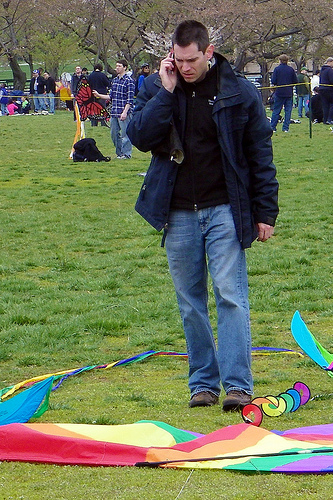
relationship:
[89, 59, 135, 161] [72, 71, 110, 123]
people holding butterfly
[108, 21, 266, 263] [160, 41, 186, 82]
guy talking on a cell phone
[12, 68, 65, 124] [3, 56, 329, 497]
people gathering on a field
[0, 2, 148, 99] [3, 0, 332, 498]
trees growing in a park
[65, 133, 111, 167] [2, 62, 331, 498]
bag sitting on ground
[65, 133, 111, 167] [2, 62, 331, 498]
bag on ground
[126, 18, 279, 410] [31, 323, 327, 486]
person standing on ground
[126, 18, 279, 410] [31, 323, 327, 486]
person on ground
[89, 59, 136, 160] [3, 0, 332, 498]
people gathering in park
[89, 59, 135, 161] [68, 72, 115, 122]
people holding kite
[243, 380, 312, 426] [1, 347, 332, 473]
tail of kite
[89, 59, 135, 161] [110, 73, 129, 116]
people wearing plaid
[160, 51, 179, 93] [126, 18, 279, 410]
hand of a person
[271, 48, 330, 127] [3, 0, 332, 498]
people standing in park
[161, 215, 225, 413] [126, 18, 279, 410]
leg of a person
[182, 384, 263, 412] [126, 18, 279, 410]
feet of a person